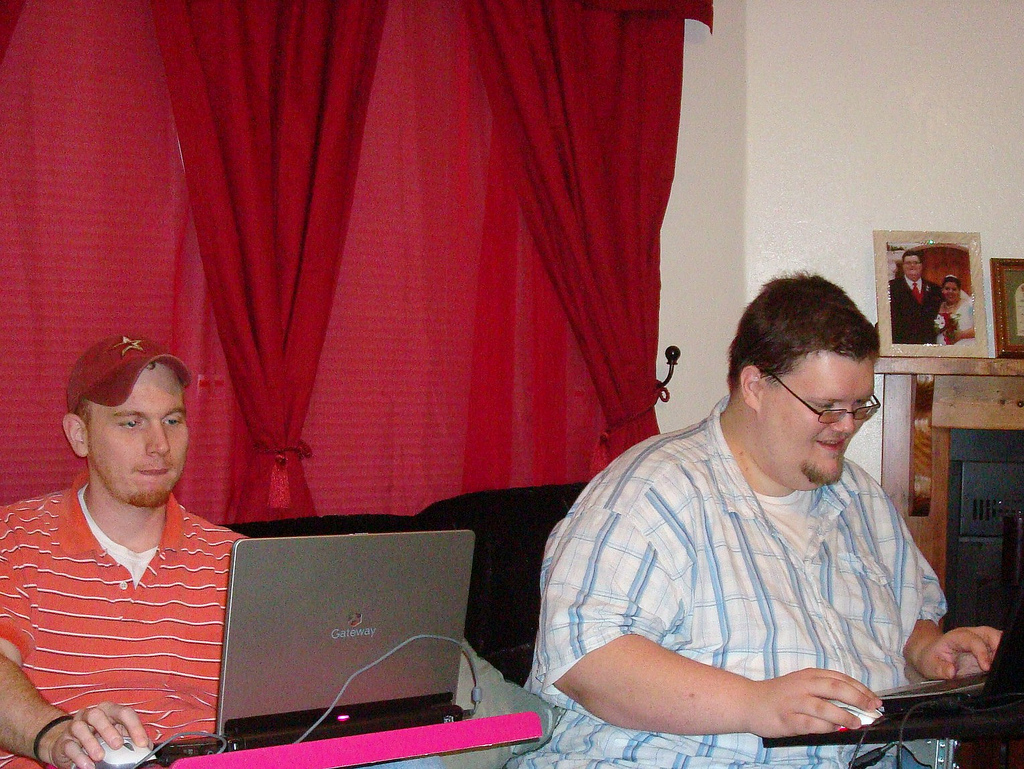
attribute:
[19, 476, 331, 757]
shirt — orange, striped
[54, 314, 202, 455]
hat — red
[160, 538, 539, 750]
laptop — silver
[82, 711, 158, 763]
mouse — white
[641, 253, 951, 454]
hair — red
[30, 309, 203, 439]
hat — red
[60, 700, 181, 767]
mouse — white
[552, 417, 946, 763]
shirt — blue stripe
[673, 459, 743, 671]
blue stripe — on shirt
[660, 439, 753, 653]
blue stripe — on shirt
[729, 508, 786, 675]
blue stripe — on shirt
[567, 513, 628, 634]
blue stripe — on shirt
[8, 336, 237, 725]
man — one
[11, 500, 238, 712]
shirt — orange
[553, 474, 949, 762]
shirt — blue, white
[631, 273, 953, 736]
man — one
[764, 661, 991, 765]
keyboard — one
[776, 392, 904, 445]
glasses — black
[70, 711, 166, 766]
mouse — white , gray, laptop 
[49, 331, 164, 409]
hat — red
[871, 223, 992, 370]
frame — white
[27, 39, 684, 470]
curtains — red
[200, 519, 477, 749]
computer — laptop , Gateway , silver 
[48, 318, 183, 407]
hat — red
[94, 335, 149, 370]
logo — star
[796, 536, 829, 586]
button — white 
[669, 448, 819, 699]
stripes — blue 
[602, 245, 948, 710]
man — one 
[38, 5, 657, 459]
curtains — bright , red , window 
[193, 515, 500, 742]
computer — laptop 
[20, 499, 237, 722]
polo — orange 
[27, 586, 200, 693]
stripes — white 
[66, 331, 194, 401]
hat — red , baseball 